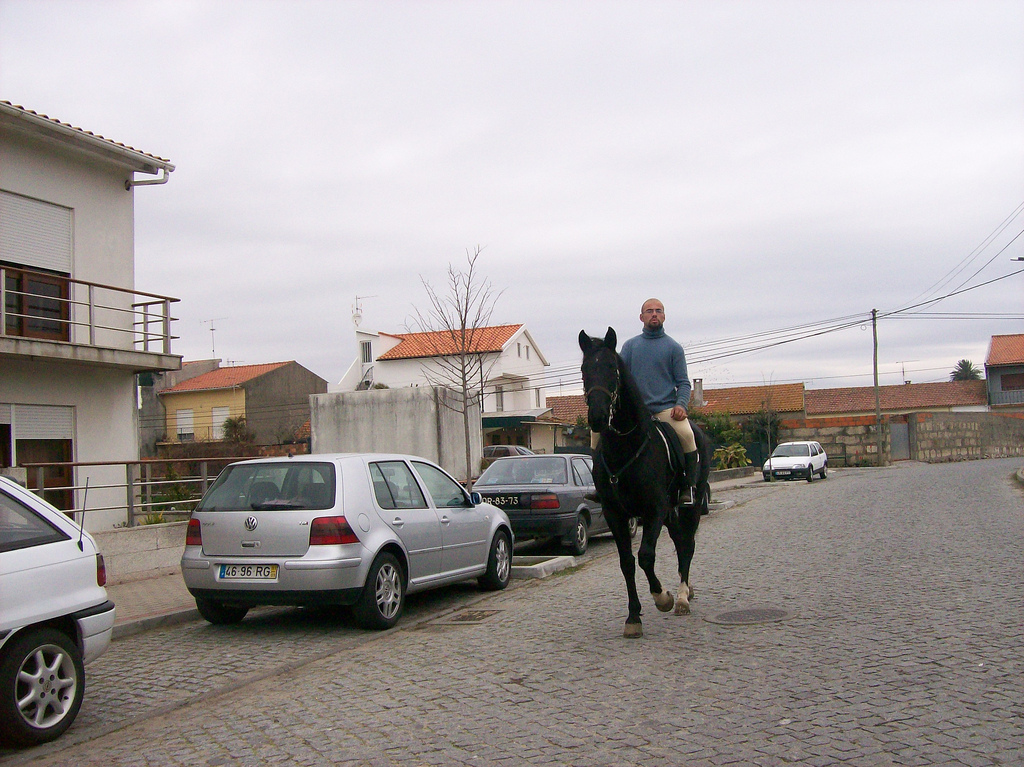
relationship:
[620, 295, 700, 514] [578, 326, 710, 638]
man on horse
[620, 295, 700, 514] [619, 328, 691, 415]
man wearing shirt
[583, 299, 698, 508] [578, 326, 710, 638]
man riding horse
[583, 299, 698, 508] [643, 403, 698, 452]
man wearing pants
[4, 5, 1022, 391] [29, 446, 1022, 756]
sky above road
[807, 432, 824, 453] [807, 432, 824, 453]
stone in wall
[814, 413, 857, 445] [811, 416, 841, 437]
stone in wall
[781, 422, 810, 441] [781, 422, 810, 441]
stone in wall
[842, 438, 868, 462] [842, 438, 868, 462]
stone in wall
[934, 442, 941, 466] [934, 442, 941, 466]
stone in wall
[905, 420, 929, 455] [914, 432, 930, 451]
stone in wall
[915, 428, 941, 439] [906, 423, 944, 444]
stone in wall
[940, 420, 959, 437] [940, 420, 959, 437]
stone in wall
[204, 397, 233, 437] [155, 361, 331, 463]
window on building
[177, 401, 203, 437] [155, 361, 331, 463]
window on building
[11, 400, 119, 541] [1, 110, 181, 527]
window on building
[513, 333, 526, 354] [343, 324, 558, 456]
window on building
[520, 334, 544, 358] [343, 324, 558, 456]
window on building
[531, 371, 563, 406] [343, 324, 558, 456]
window on building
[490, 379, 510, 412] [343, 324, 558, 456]
window on building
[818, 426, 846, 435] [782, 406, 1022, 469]
stone in wall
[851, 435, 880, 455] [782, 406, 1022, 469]
stone in wall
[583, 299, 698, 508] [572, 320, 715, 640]
man on horse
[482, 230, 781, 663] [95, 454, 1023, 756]
horse on road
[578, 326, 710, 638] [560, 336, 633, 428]
horse has head